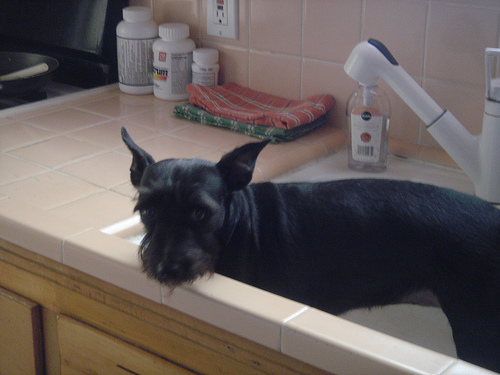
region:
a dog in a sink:
[101, 116, 497, 366]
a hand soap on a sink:
[346, 81, 396, 161]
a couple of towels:
[176, 76, 333, 142]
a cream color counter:
[2, 108, 128, 240]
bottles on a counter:
[114, 11, 208, 98]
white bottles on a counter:
[112, 8, 219, 93]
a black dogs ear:
[215, 133, 278, 192]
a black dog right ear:
[119, 126, 156, 190]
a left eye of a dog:
[186, 200, 211, 223]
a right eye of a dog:
[133, 197, 165, 227]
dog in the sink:
[106, 160, 481, 284]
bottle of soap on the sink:
[313, 82, 396, 163]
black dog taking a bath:
[113, 160, 455, 288]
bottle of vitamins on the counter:
[151, 19, 183, 86]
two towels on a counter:
[194, 80, 308, 153]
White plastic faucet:
[338, 33, 495, 163]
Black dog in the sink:
[111, 128, 495, 318]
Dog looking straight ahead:
[105, 133, 245, 271]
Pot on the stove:
[13, 36, 57, 97]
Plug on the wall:
[201, 0, 242, 36]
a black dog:
[109, 125, 495, 367]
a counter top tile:
[0, 96, 341, 242]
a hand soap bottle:
[347, 72, 396, 175]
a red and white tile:
[185, 70, 337, 130]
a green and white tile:
[168, 103, 325, 148]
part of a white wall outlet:
[203, 0, 239, 42]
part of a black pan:
[3, 42, 60, 90]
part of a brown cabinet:
[52, 305, 219, 373]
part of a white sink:
[339, 297, 458, 352]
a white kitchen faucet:
[343, 45, 498, 200]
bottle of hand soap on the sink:
[340, 75, 390, 172]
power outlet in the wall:
[205, 8, 240, 37]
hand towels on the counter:
[179, 82, 336, 139]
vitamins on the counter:
[114, 5, 216, 105]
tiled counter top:
[25, 114, 107, 191]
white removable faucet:
[336, 36, 458, 144]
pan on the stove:
[2, 46, 56, 91]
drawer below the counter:
[0, 298, 40, 371]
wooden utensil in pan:
[4, 62, 52, 77]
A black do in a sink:
[116, 116, 497, 323]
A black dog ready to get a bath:
[114, 113, 494, 303]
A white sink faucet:
[341, 4, 497, 195]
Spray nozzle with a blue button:
[350, 32, 433, 122]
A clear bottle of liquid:
[339, 76, 394, 165]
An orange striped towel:
[188, 85, 313, 122]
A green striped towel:
[175, 101, 290, 147]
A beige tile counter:
[57, 95, 119, 240]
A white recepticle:
[201, 3, 252, 43]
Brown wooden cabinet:
[33, 258, 145, 374]